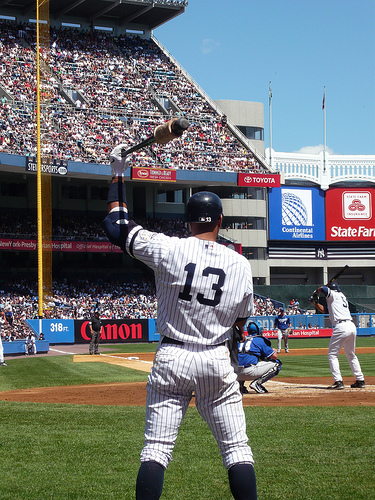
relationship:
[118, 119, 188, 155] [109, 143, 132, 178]
baseball bat in hand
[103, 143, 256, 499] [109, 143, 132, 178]
batter has hand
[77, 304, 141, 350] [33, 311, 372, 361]
advertising on wall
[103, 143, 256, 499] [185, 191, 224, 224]
batter wearing cap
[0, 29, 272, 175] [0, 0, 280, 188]
audience in bleachers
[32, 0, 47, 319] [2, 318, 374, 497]
pole on ball field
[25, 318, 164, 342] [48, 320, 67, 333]
blue wall says 318 ft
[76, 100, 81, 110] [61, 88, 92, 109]
person in stairway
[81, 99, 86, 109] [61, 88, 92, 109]
person in stairway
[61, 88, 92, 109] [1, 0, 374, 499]
stairway of stadium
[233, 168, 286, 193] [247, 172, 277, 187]
banner with advertisement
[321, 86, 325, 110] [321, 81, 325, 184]
flag on pole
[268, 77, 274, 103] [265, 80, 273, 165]
flag on pole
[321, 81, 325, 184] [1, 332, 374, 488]
pole above field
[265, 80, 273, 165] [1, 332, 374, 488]
pole above field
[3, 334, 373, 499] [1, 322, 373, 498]
lawn on field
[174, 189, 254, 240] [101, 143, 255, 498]
helmet on batter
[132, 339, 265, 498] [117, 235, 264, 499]
pants on uniform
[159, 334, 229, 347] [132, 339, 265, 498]
belt around pants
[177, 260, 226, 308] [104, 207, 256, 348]
13 on shirt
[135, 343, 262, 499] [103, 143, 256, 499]
legs of batter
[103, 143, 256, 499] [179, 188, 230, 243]
batter wearing cap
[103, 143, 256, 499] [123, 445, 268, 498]
batter wearing socks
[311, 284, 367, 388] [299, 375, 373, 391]
man wearing shoe